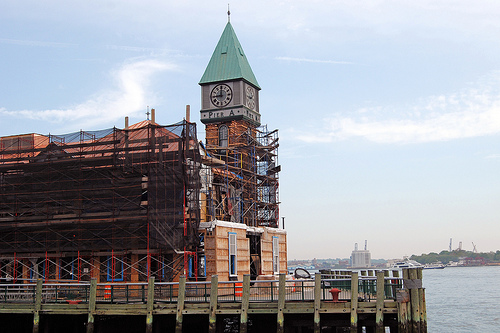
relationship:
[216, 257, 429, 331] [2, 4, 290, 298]
pier in front of building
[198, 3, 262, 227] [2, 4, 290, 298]
tower on building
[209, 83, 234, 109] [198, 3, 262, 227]
clock on tower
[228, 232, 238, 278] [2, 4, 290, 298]
window on building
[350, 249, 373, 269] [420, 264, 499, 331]
building across water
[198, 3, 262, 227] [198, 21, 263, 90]
tower has roof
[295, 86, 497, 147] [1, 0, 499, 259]
cloud in sky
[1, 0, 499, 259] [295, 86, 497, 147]
sky has cloud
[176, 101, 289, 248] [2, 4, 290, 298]
scaffolding across building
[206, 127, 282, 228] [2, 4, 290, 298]
scaffolding across building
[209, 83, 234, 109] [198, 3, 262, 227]
clock in tower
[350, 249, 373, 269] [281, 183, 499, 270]
building in distance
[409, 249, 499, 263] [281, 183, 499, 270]
trees in distance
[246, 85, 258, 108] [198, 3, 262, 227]
clock on tower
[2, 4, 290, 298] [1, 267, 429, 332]
building on dock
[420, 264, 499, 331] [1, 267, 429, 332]
water under dock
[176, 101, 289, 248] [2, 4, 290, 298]
scaffolding against building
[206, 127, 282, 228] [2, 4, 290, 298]
scaffolding against building